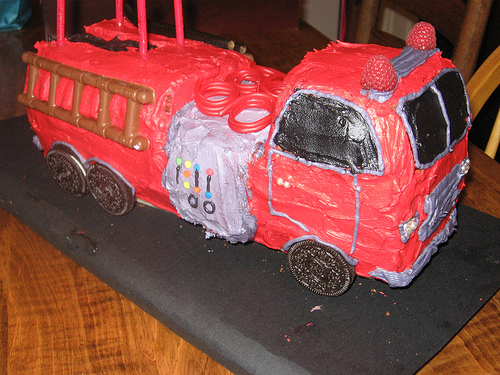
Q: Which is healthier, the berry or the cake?
A: The berry is healthier than the cake.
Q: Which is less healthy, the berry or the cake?
A: The cake is less healthy than the berry.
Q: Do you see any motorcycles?
A: No, there are no motorcycles.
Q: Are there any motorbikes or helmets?
A: No, there are no motorbikes or helmets.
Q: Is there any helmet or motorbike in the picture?
A: No, there are no motorcycles or helmets.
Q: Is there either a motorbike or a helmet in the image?
A: No, there are no motorcycles or helmets.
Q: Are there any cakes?
A: Yes, there is a cake.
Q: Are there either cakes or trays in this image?
A: Yes, there is a cake.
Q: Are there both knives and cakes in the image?
A: No, there is a cake but no knives.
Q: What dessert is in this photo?
A: The dessert is a cake.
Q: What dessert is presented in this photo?
A: The dessert is a cake.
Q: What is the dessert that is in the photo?
A: The dessert is a cake.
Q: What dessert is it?
A: The dessert is a cake.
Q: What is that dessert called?
A: This is a cake.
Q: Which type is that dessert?
A: This is a cake.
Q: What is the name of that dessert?
A: This is a cake.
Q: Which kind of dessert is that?
A: This is a cake.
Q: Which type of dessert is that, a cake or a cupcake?
A: This is a cake.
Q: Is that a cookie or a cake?
A: That is a cake.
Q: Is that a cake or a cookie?
A: That is a cake.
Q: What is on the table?
A: The cake is on the table.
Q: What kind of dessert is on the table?
A: The dessert is a cake.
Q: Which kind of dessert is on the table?
A: The dessert is a cake.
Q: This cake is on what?
A: The cake is on the table.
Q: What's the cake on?
A: The cake is on the table.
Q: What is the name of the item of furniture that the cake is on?
A: The piece of furniture is a table.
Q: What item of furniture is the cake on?
A: The cake is on the table.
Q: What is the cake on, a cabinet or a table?
A: The cake is on a table.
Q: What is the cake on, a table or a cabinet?
A: The cake is on a table.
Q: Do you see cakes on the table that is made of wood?
A: Yes, there is a cake on the table.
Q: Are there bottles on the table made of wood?
A: No, there is a cake on the table.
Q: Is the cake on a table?
A: Yes, the cake is on a table.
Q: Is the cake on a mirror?
A: No, the cake is on a table.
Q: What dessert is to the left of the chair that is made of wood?
A: The dessert is a cake.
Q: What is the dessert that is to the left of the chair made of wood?
A: The dessert is a cake.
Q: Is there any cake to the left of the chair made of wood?
A: Yes, there is a cake to the left of the chair.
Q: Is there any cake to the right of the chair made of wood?
A: No, the cake is to the left of the chair.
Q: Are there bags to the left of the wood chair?
A: No, there is a cake to the left of the chair.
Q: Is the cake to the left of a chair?
A: Yes, the cake is to the left of a chair.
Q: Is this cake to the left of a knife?
A: No, the cake is to the left of a chair.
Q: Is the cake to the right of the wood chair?
A: No, the cake is to the left of the chair.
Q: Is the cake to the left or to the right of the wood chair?
A: The cake is to the left of the chair.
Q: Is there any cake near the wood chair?
A: Yes, there is a cake near the chair.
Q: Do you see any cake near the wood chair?
A: Yes, there is a cake near the chair.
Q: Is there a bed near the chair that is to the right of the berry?
A: No, there is a cake near the chair.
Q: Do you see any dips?
A: No, there are no dips.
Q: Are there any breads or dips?
A: No, there are no dips or breads.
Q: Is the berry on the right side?
A: Yes, the berry is on the right of the image.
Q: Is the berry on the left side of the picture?
A: No, the berry is on the right of the image.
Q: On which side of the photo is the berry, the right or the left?
A: The berry is on the right of the image.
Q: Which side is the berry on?
A: The berry is on the right of the image.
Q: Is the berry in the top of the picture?
A: Yes, the berry is in the top of the image.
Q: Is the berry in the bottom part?
A: No, the berry is in the top of the image.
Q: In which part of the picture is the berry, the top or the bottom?
A: The berry is in the top of the image.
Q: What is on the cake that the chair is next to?
A: The berry is on the cake.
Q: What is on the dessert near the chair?
A: The berry is on the cake.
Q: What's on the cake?
A: The berry is on the cake.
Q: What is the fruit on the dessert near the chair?
A: The fruit is a berry.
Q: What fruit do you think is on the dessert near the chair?
A: The fruit is a berry.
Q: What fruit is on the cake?
A: The fruit is a berry.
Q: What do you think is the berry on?
A: The berry is on the cake.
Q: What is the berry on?
A: The berry is on the cake.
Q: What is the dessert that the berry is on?
A: The dessert is a cake.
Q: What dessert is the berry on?
A: The berry is on the cake.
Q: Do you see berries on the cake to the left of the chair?
A: Yes, there is a berry on the cake.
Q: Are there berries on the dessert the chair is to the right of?
A: Yes, there is a berry on the cake.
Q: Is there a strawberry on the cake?
A: No, there is a berry on the cake.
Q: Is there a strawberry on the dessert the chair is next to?
A: No, there is a berry on the cake.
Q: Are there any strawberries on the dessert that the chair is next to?
A: No, there is a berry on the cake.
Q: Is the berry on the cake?
A: Yes, the berry is on the cake.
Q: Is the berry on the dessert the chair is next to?
A: Yes, the berry is on the cake.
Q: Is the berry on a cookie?
A: No, the berry is on the cake.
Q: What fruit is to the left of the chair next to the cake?
A: The fruit is a berry.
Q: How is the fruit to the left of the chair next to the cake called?
A: The fruit is a berry.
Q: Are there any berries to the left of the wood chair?
A: Yes, there is a berry to the left of the chair.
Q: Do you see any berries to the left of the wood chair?
A: Yes, there is a berry to the left of the chair.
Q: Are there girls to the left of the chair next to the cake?
A: No, there is a berry to the left of the chair.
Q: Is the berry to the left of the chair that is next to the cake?
A: Yes, the berry is to the left of the chair.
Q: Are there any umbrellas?
A: No, there are no umbrellas.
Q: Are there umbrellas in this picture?
A: No, there are no umbrellas.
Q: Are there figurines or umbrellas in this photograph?
A: No, there are no umbrellas or figurines.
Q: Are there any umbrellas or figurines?
A: No, there are no umbrellas or figurines.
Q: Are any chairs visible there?
A: Yes, there is a chair.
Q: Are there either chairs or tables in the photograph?
A: Yes, there is a chair.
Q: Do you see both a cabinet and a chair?
A: No, there is a chair but no cabinets.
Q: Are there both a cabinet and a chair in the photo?
A: No, there is a chair but no cabinets.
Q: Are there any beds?
A: No, there are no beds.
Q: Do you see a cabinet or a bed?
A: No, there are no beds or cabinets.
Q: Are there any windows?
A: Yes, there is a window.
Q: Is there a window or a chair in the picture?
A: Yes, there is a window.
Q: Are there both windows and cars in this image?
A: No, there is a window but no cars.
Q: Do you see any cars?
A: No, there are no cars.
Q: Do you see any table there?
A: Yes, there is a table.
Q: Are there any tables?
A: Yes, there is a table.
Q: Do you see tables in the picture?
A: Yes, there is a table.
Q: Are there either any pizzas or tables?
A: Yes, there is a table.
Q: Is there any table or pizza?
A: Yes, there is a table.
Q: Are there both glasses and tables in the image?
A: No, there is a table but no glasses.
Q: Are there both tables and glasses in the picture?
A: No, there is a table but no glasses.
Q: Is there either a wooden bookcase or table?
A: Yes, there is a wood table.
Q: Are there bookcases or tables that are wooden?
A: Yes, the table is wooden.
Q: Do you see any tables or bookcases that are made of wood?
A: Yes, the table is made of wood.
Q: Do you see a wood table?
A: Yes, there is a wood table.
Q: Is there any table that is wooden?
A: Yes, there is a table that is wooden.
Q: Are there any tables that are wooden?
A: Yes, there is a table that is wooden.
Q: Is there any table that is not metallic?
A: Yes, there is a wooden table.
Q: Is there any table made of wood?
A: Yes, there is a table that is made of wood.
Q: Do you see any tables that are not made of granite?
A: Yes, there is a table that is made of wood.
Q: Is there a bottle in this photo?
A: No, there are no bottles.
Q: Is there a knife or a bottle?
A: No, there are no bottles or knives.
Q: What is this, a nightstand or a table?
A: This is a table.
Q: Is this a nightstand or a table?
A: This is a table.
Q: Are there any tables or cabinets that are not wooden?
A: No, there is a table but it is wooden.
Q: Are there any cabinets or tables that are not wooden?
A: No, there is a table but it is wooden.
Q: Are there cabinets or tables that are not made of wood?
A: No, there is a table but it is made of wood.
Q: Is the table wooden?
A: Yes, the table is wooden.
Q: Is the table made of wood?
A: Yes, the table is made of wood.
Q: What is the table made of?
A: The table is made of wood.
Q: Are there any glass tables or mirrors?
A: No, there is a table but it is wooden.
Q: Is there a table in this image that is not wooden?
A: No, there is a table but it is wooden.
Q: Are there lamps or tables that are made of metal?
A: No, there is a table but it is made of wood.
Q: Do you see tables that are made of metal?
A: No, there is a table but it is made of wood.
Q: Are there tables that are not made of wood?
A: No, there is a table but it is made of wood.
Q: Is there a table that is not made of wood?
A: No, there is a table but it is made of wood.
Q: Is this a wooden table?
A: Yes, this is a wooden table.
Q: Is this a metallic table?
A: No, this is a wooden table.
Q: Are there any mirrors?
A: No, there are no mirrors.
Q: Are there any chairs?
A: Yes, there is a chair.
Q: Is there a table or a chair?
A: Yes, there is a chair.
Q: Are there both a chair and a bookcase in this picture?
A: No, there is a chair but no bookcases.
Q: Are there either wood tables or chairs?
A: Yes, there is a wood chair.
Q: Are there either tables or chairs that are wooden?
A: Yes, the chair is wooden.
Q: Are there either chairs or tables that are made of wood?
A: Yes, the chair is made of wood.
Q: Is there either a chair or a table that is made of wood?
A: Yes, the chair is made of wood.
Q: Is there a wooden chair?
A: Yes, there is a wood chair.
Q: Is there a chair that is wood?
A: Yes, there is a wood chair.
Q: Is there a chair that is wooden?
A: Yes, there is a chair that is wooden.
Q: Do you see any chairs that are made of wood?
A: Yes, there is a chair that is made of wood.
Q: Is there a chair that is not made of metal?
A: Yes, there is a chair that is made of wood.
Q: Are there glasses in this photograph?
A: No, there are no glasses.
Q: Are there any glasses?
A: No, there are no glasses.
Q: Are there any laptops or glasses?
A: No, there are no glasses or laptops.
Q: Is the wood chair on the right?
A: Yes, the chair is on the right of the image.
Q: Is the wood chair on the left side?
A: No, the chair is on the right of the image.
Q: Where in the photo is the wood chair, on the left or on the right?
A: The chair is on the right of the image.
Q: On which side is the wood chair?
A: The chair is on the right of the image.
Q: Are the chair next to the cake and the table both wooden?
A: Yes, both the chair and the table are wooden.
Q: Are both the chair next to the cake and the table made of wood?
A: Yes, both the chair and the table are made of wood.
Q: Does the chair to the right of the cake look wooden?
A: Yes, the chair is wooden.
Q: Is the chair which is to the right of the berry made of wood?
A: Yes, the chair is made of wood.